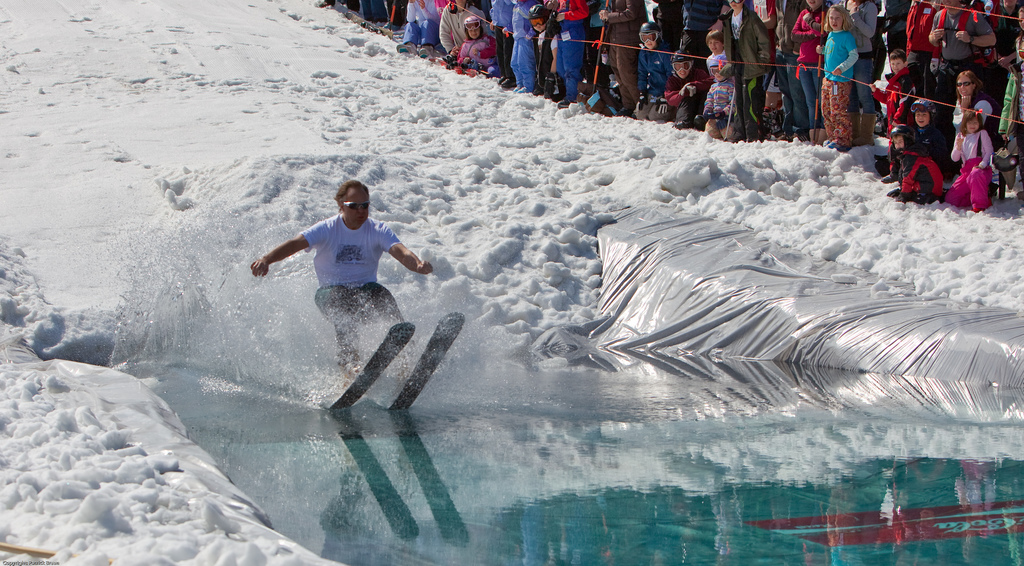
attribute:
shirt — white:
[242, 187, 457, 365]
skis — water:
[281, 331, 487, 415]